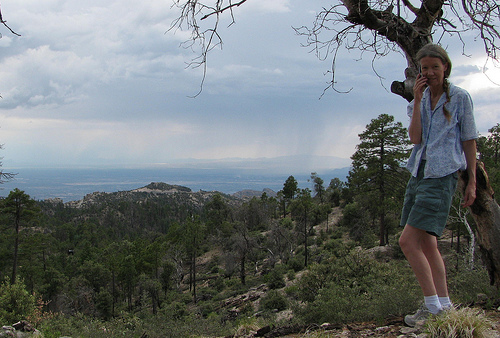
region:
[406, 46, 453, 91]
head of a person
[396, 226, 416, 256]
knee of a person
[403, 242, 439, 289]
leg of a person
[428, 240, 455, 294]
leg of a person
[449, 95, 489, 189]
arm of a person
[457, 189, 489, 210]
hand of a person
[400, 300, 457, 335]
feet of a person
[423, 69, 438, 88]
mouth of a person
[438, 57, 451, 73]
ear of a person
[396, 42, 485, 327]
Woman standing in front of a tree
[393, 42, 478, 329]
A woman in green shorts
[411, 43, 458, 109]
A woman talking on a cell phone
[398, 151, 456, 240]
A pair of green shorts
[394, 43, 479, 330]
A woman talking on her phone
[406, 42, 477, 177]
Woman in a light blue blouse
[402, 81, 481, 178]
A light blue blouse on a woman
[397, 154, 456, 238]
Green shorts on a woman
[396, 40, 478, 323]
A woman standing outside under a tree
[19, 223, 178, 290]
The trees are the color green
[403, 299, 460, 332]
The feet of the woman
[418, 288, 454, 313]
The woman has on white socks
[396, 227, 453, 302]
The legs of the woman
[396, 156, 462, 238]
The shorts of the woman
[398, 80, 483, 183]
The woman has on a floral shirt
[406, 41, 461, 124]
The woman has blonde hair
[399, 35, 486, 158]
The woman is on a cell phone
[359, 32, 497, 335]
The woman is on the ground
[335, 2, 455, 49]
The tree trunk is the color brown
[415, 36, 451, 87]
woman has grey hair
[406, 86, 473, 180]
woman has blue shirt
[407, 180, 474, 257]
woman has green shorts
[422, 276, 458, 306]
woman has white socks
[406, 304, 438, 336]
woman has grey shoes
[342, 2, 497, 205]
grey tree trunk behind woman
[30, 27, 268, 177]
grey and pink sky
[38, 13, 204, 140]
heavy rain clouds in sky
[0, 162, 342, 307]
green trees in valley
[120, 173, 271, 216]
tall hill in distance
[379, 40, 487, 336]
woman standing up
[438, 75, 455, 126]
hair laying over the shoulder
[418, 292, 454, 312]
white sox around the ankles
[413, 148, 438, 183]
bottom of the shirt is hanging open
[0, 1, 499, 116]
thick clouds in the sky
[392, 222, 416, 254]
knee is bent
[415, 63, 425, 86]
hand holding a cellphone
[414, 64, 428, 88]
phone lifted up to the face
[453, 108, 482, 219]
arm is down by side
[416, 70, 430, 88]
fingers on the phone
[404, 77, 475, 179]
shirt is worn by human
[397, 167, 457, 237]
shorts are worn by human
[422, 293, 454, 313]
socks are worn by human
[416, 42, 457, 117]
hair is worn long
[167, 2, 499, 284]
bare tree behind human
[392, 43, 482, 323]
human in front of tree